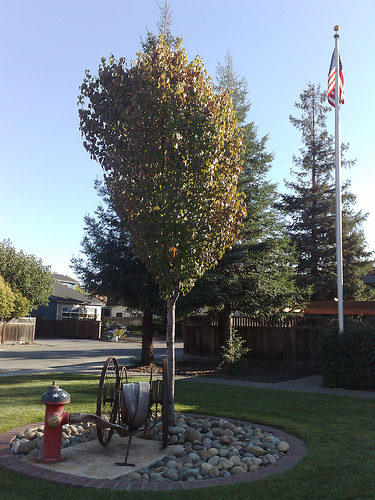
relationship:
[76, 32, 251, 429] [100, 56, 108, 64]
tree has leaf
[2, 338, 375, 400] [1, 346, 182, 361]
pavement has shadow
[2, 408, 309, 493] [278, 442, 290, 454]
circle has rock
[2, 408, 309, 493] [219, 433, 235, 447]
circle has rock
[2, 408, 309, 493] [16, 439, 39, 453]
circle has rock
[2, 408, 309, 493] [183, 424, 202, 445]
circle has rock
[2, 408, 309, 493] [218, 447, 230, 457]
circle has rock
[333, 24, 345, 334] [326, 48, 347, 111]
post has flag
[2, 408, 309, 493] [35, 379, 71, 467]
circle has hydrant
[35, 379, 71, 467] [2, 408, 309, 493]
hydrant in circle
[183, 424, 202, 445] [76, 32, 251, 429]
rock next to tree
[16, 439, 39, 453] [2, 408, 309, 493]
rock in circle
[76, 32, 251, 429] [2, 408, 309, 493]
tree in circle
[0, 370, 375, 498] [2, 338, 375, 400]
grass next to pavement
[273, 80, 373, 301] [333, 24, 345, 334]
pine tree behind post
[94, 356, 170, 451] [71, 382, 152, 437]
hose  organizer has hose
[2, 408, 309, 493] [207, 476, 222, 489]
circle has brick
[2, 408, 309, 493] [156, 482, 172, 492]
circle has brick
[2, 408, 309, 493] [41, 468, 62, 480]
circle has brick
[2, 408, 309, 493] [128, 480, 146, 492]
circle has brick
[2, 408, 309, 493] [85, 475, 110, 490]
circle has brick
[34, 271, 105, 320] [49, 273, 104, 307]
house has roof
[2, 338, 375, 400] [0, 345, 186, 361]
pavement has road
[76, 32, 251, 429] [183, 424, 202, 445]
tree has rock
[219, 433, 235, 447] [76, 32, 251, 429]
rock next to tree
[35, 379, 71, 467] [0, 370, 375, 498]
hydrant in grass